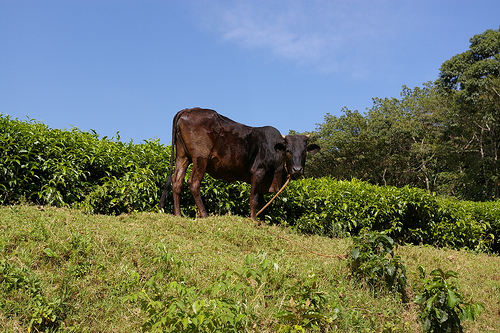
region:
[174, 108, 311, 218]
A cow standing near the bushes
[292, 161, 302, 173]
The nose of the cow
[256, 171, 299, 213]
A rope connected to the cow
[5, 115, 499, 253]
Bushes behind the cow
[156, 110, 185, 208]
The tail of the cow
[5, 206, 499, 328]
Grass beneath the cow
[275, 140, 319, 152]
The ears of the cow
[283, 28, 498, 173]
Trees near the cow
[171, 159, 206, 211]
The back legs of the cow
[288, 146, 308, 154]
The eyes of the cow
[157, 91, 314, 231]
Skinny brown cow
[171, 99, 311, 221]
Cow looking towards camera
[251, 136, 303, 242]
Cow wearing brown rope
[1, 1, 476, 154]
Clear blue and white sky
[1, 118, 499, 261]
Hedged green bushes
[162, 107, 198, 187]
Brown cow tail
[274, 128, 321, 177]
Black cow head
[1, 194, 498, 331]
Green pasture field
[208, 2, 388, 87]
Small white puffy cloud in the sky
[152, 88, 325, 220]
Cow looking straight at camera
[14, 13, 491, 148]
a plain blue sky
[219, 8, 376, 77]
a fuzzy cloud in the sky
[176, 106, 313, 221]
an animal outside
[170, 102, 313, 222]
the animal is dark brown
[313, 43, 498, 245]
a lot of trees behind the animal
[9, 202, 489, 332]
green and tan looking grass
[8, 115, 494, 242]
bushes behind the animal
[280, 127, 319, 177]
the face of the animal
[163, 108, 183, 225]
the tail of the animal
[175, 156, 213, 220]
the legs of the animal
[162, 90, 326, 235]
black and brown colored cow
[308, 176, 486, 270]
green foliage hedge row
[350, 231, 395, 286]
tin green bush on the field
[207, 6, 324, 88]
wispy white clouds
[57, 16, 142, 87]
sky without clouds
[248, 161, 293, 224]
rope tied to a cows neck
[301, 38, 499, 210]
row of trees by a field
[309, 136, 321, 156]
ear on a cow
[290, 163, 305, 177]
nose on a cow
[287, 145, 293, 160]
eye on a cow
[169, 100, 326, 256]
a cow is focusing the camera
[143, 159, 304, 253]
cow is standing in the grass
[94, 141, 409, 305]
dirt with plants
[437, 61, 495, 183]
trees with its branches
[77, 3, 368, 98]
sky with clouds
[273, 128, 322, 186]
head of the cow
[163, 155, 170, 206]
tail of the cow with fringes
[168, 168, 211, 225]
leg of the cow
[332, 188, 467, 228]
green leaves with plants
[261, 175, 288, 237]
rope of the cow